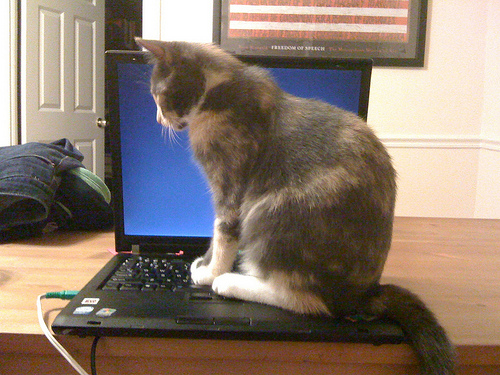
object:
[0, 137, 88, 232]
jeans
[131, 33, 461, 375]
cat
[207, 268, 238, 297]
paws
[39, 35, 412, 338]
computer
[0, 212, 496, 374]
table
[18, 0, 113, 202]
door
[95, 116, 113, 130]
knob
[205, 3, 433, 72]
poster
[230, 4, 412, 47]
flag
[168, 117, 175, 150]
whiskers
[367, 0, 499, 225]
walls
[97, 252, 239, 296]
keyboard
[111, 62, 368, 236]
screen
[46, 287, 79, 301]
cord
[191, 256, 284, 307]
feet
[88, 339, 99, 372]
wire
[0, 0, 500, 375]
room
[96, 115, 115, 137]
doorknob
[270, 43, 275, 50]
words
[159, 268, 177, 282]
letters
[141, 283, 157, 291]
keys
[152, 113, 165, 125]
nose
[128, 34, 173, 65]
ear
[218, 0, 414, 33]
stripe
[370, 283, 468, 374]
tail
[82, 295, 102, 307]
sticker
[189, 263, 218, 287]
paw